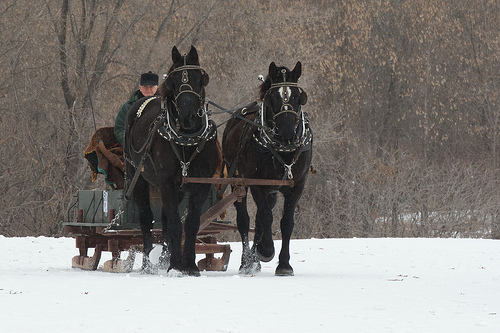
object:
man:
[116, 70, 161, 140]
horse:
[129, 39, 229, 275]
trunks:
[60, 176, 76, 226]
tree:
[19, 5, 123, 218]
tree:
[336, 4, 457, 242]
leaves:
[350, 20, 370, 41]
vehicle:
[73, 246, 238, 279]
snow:
[0, 249, 483, 331]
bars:
[182, 171, 295, 191]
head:
[136, 68, 160, 99]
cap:
[137, 71, 158, 88]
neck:
[165, 122, 215, 152]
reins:
[141, 113, 227, 148]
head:
[254, 62, 312, 144]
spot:
[276, 82, 291, 104]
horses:
[219, 56, 318, 279]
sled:
[62, 188, 242, 277]